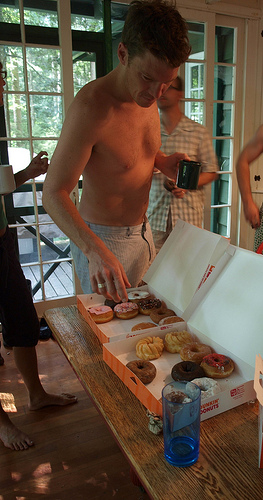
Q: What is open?
A: Boxes.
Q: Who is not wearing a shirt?
A: A man.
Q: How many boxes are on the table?
A: Two.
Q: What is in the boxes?
A: Donuts.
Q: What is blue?
A: A glass.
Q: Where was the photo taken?
A: In a dining room.